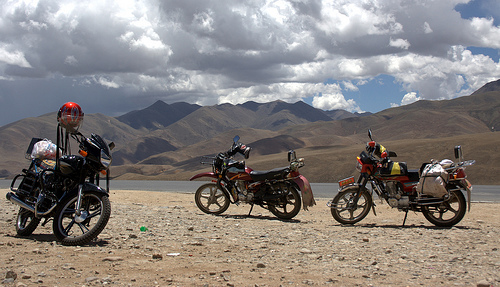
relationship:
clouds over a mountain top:
[0, 7, 367, 96] [0, 86, 483, 189]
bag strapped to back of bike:
[415, 156, 454, 201] [327, 127, 477, 227]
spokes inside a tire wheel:
[201, 186, 224, 207] [189, 179, 230, 215]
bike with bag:
[321, 125, 466, 233] [411, 148, 450, 198]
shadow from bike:
[327, 217, 477, 234] [327, 127, 477, 227]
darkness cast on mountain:
[142, 106, 176, 117] [108, 93, 198, 126]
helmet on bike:
[50, 94, 87, 134] [3, 122, 120, 244]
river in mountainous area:
[0, 174, 484, 202] [10, 61, 474, 177]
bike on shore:
[4, 122, 111, 246] [2, 179, 498, 284]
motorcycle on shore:
[189, 135, 319, 219] [2, 179, 498, 284]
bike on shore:
[327, 127, 477, 227] [2, 179, 498, 284]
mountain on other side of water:
[0, 78, 500, 185] [4, 173, 498, 200]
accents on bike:
[365, 138, 389, 155] [327, 127, 477, 227]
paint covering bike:
[389, 159, 402, 173] [324, 127, 474, 229]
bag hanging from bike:
[416, 160, 449, 198] [324, 127, 474, 229]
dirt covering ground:
[0, 183, 484, 283] [1, 184, 484, 284]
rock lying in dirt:
[255, 261, 265, 268] [0, 183, 484, 283]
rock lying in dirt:
[257, 244, 268, 249] [0, 183, 484, 283]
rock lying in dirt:
[300, 246, 311, 253] [0, 183, 484, 283]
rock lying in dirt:
[305, 251, 322, 260] [0, 183, 484, 283]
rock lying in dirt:
[167, 250, 179, 257] [0, 183, 484, 283]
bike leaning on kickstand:
[327, 127, 477, 227] [399, 208, 409, 227]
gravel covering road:
[0, 184, 484, 284] [1, 183, 484, 284]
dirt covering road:
[0, 183, 484, 283] [1, 183, 484, 284]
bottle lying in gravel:
[138, 223, 148, 230] [0, 184, 484, 284]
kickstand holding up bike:
[400, 206, 409, 226] [324, 127, 474, 229]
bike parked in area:
[4, 122, 111, 246] [1, 75, 483, 284]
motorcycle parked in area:
[189, 132, 314, 219] [1, 75, 483, 284]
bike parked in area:
[327, 127, 477, 227] [1, 75, 483, 284]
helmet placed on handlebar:
[56, 101, 85, 128] [52, 121, 84, 142]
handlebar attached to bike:
[52, 121, 84, 142] [4, 122, 111, 246]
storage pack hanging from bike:
[433, 156, 454, 170] [327, 127, 477, 227]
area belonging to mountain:
[110, 95, 201, 131] [2, 73, 484, 186]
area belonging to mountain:
[108, 132, 178, 167] [2, 73, 484, 186]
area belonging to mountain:
[268, 115, 293, 128] [2, 73, 484, 186]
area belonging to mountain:
[265, 96, 334, 123] [2, 73, 484, 186]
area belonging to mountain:
[236, 98, 262, 113] [2, 73, 484, 186]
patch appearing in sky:
[325, 73, 412, 110] [0, 1, 484, 123]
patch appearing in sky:
[299, 91, 321, 104] [0, 1, 484, 123]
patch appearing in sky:
[463, 43, 484, 61] [0, 1, 484, 123]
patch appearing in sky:
[451, 1, 483, 20] [0, 1, 484, 123]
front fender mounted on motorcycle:
[187, 170, 240, 205] [189, 132, 314, 219]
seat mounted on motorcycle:
[246, 165, 289, 181] [189, 132, 314, 219]